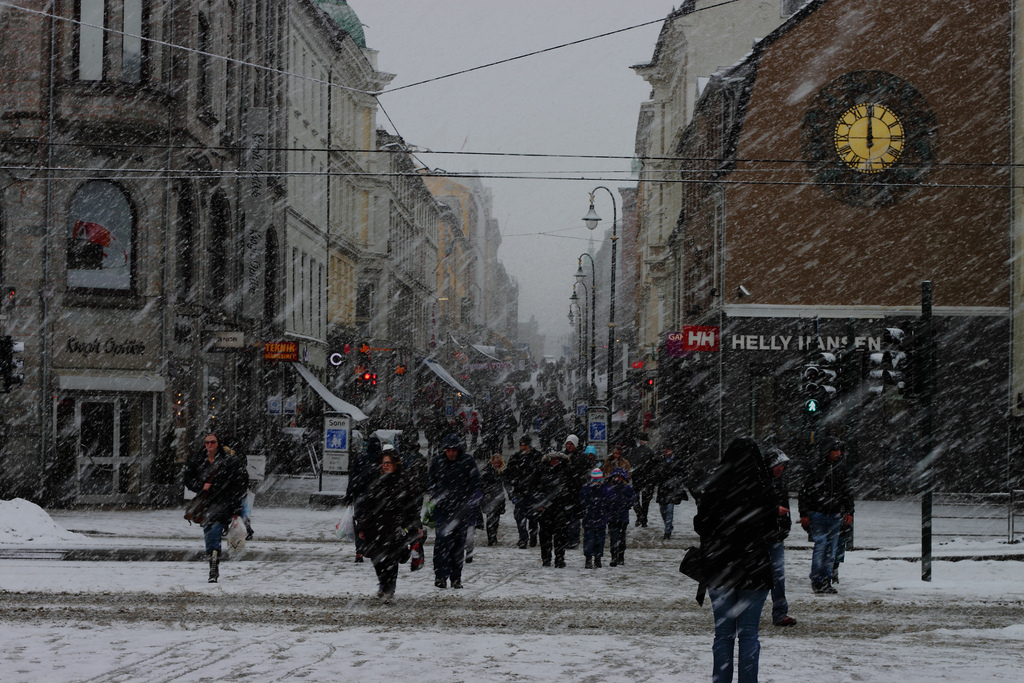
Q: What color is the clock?
A: Yellow.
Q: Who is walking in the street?
A: Many people.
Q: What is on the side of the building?
A: Clock.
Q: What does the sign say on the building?
A: Helly hansen.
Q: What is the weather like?
A: Snowy.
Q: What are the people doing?
A: Walking.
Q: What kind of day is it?
A: Snowy.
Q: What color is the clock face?
A: Yellow.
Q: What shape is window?
A: Rounded.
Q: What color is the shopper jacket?
A: Black.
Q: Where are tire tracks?
A: In snow.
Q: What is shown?
A: Buildings.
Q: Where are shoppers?
A: On street.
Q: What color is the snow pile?
A: White.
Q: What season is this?
A: Winter.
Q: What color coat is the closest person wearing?
A: Black.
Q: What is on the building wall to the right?
A: A clock.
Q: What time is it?
A: 12:00.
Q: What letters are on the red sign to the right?
A: HH.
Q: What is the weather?
A: Snowing.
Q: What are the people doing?
A: Walking.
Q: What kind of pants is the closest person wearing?
A: Blue jeans.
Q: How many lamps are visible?
A: Four.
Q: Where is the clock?
A: On the wall of the building to the left.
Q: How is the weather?
A: Cloudy and cold.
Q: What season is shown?
A: Winter.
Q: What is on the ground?
A: Snow.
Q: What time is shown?
A: 12.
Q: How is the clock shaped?
A: As a circle.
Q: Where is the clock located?
A: In a building.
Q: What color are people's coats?
A: Black.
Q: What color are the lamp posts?
A: Black.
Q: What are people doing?
A: Walking.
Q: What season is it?
A: Winter.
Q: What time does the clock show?
A: 12 o'clock.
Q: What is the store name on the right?
A: Helly Hansen.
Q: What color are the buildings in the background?
A: Gray, white, and brown.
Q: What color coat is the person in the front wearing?
A: Black.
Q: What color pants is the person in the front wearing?
A: Blue.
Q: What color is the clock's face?
A: White.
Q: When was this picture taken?
A: At noon.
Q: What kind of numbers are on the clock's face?
A: Roman numerals.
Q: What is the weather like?
A: Snowy.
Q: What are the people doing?
A: Walking.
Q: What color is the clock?
A: Gold.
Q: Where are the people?
A: The street.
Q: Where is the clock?
A: The building.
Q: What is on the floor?
A: Snow.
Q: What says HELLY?
A: The sign.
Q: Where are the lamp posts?
A: The poles.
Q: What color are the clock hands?
A: Black.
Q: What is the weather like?
A: Snowy.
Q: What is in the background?
A: A city street and buildings.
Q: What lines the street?
A: Rows of buildings.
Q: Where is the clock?
A: On the side of the brick building.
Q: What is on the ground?
A: Snow.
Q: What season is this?
A: Winter.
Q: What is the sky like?
A: Overcast.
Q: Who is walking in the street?
A: Pedestrians.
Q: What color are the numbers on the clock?
A: Black.